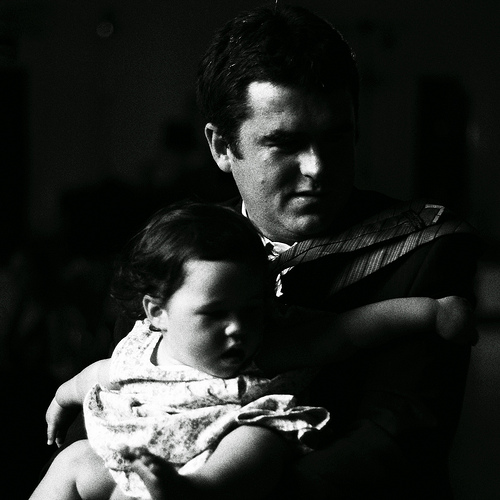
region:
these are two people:
[40, 28, 473, 486]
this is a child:
[109, 210, 294, 486]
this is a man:
[196, 3, 376, 236]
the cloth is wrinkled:
[110, 380, 171, 437]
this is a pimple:
[249, 174, 269, 185]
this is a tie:
[323, 207, 447, 274]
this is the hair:
[257, 20, 294, 62]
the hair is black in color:
[217, 56, 232, 85]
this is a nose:
[296, 147, 327, 185]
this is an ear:
[205, 120, 232, 179]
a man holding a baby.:
[190, 39, 349, 248]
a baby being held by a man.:
[33, 214, 375, 496]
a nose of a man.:
[277, 123, 337, 193]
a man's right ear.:
[197, 109, 232, 187]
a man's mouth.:
[273, 177, 343, 216]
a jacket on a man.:
[221, 179, 472, 426]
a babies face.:
[172, 256, 282, 368]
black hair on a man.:
[184, 14, 376, 161]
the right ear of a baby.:
[135, 282, 175, 339]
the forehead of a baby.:
[170, 254, 251, 308]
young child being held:
[70, 197, 335, 489]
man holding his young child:
[72, 78, 390, 498]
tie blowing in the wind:
[271, 187, 478, 302]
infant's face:
[137, 200, 274, 379]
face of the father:
[194, 6, 369, 237]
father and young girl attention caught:
[123, 8, 407, 384]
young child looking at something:
[19, 199, 484, 497]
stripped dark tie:
[248, 192, 492, 290]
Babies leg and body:
[21, 350, 318, 497]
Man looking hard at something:
[181, 8, 382, 243]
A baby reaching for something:
[87, 205, 320, 460]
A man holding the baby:
[205, 26, 477, 326]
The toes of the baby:
[105, 431, 181, 487]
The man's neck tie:
[235, 221, 485, 261]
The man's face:
[195, 37, 350, 217]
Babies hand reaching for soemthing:
[320, 280, 475, 355]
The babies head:
[95, 192, 265, 368]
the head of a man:
[181, 11, 386, 236]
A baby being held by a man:
[81, 20, 361, 472]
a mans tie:
[287, 186, 489, 291]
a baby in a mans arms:
[50, 175, 298, 459]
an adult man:
[194, 55, 350, 255]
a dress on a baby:
[47, 297, 301, 489]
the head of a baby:
[81, 170, 296, 422]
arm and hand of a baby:
[30, 342, 117, 457]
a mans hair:
[178, 11, 369, 161]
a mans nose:
[290, 141, 345, 202]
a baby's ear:
[131, 285, 169, 331]